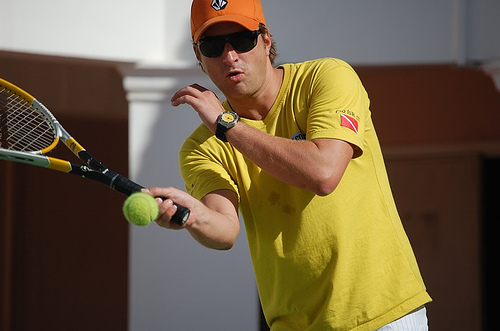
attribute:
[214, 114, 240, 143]
wrist — man's, black, tied, yellow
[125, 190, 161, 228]
ball — green, tennis, yellow, in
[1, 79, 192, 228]
racket — tennis, black, tan, orange, yellow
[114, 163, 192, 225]
handle — black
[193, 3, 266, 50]
cap — orange, baseball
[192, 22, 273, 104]
head — man's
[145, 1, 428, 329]
man — playing, tennis, wearing, holding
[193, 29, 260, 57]
sunglasses — black, pair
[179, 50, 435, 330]
shirt — yellow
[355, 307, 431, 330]
pants — white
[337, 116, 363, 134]
logo — red, square, pink, white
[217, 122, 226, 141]
band — black